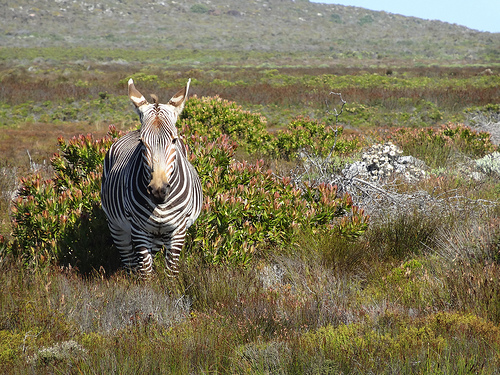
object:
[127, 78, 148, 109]
ear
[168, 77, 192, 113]
ear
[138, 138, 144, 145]
eye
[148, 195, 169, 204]
mouth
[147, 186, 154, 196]
nostril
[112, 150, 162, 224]
stripes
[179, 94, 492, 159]
bushes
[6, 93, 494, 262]
flowers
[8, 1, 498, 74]
hill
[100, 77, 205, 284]
zebra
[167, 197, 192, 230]
stripes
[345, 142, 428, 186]
rocks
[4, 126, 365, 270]
bush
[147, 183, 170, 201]
nose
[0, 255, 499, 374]
grass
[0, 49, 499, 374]
field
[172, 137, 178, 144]
eye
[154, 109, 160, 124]
hair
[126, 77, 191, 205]
head